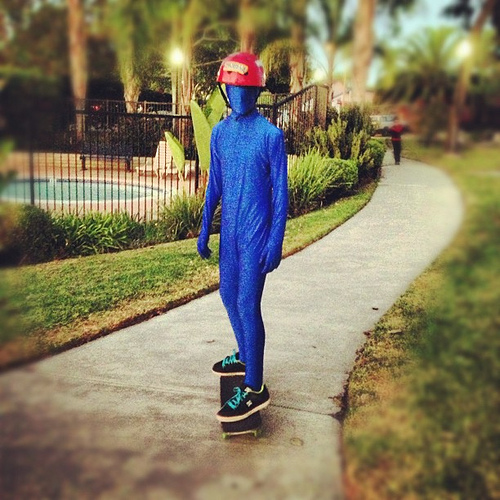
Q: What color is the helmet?
A: Red.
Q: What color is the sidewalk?
A: Grey.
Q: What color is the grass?
A: Green.